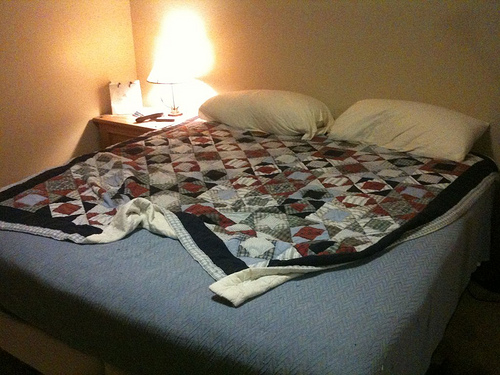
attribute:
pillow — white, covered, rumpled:
[199, 89, 333, 142]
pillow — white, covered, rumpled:
[327, 97, 491, 164]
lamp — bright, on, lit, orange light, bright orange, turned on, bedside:
[147, 56, 184, 118]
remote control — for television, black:
[135, 113, 163, 123]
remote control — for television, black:
[155, 117, 176, 123]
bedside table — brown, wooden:
[92, 106, 198, 149]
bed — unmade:
[0, 116, 498, 375]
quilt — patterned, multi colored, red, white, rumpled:
[0, 115, 499, 308]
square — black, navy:
[302, 189, 327, 200]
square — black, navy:
[203, 168, 226, 181]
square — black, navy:
[323, 147, 345, 159]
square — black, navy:
[431, 162, 458, 173]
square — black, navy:
[235, 137, 257, 144]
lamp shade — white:
[146, 58, 186, 85]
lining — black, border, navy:
[1, 116, 499, 276]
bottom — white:
[88, 198, 307, 310]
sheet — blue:
[1, 182, 499, 375]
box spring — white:
[1, 310, 135, 374]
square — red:
[53, 202, 81, 215]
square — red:
[292, 223, 325, 241]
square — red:
[359, 180, 387, 191]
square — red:
[192, 135, 210, 144]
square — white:
[276, 153, 297, 164]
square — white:
[417, 172, 443, 185]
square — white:
[240, 236, 276, 256]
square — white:
[377, 168, 403, 179]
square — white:
[16, 193, 48, 206]